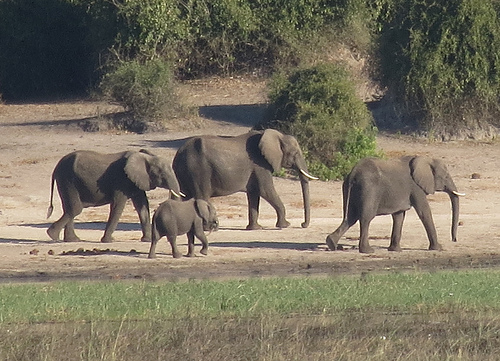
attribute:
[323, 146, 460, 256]
elephant — baby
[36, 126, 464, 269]
elephants — grey 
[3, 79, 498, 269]
brown dirt — light brown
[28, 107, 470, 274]
elephants — herd, gray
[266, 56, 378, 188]
bush — large 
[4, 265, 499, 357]
grass — green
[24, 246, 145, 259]
pile — large